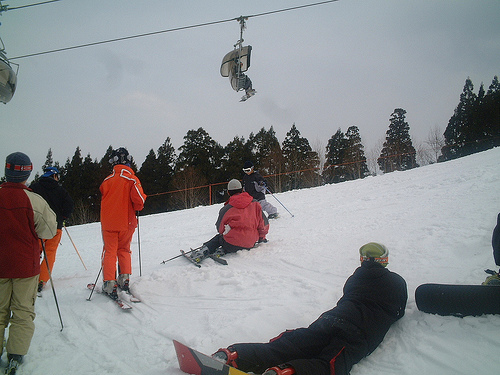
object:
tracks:
[49, 288, 214, 375]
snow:
[10, 141, 499, 374]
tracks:
[396, 160, 499, 232]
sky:
[0, 1, 498, 171]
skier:
[92, 146, 144, 297]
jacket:
[97, 163, 148, 233]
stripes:
[100, 162, 147, 204]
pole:
[136, 208, 144, 276]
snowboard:
[171, 339, 249, 374]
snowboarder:
[210, 239, 408, 374]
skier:
[1, 147, 63, 374]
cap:
[4, 150, 35, 183]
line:
[0, 0, 343, 63]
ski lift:
[217, 15, 260, 105]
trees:
[1, 73, 499, 230]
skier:
[180, 176, 279, 268]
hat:
[356, 242, 391, 267]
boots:
[214, 341, 330, 374]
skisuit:
[93, 163, 147, 284]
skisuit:
[201, 193, 274, 259]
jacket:
[216, 190, 267, 247]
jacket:
[0, 178, 61, 282]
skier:
[236, 160, 282, 225]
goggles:
[238, 167, 255, 175]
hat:
[241, 160, 254, 170]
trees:
[412, 124, 447, 168]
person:
[230, 61, 258, 104]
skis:
[84, 275, 146, 314]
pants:
[98, 227, 139, 284]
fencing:
[2, 141, 415, 231]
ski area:
[14, 146, 499, 374]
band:
[4, 162, 34, 172]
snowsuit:
[94, 162, 148, 280]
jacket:
[307, 259, 408, 348]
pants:
[1, 273, 41, 356]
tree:
[377, 103, 421, 174]